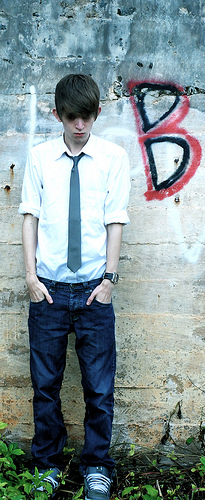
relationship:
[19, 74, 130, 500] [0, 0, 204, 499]
young man standing against wall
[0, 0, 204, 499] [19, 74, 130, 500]
wall behind young man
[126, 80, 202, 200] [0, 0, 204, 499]
graffiti painted on wall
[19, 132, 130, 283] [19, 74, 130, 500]
shirt worn on young man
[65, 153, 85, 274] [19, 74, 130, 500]
tie worn on young man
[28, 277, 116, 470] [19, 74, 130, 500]
jeans worn on young man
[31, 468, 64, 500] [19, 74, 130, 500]
skater shoe worn on young man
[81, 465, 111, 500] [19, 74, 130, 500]
skater shoe worn on young man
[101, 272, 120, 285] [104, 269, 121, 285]
watch worn on wrist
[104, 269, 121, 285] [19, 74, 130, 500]
wrist of young man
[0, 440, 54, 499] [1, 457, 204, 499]
plants growing on ground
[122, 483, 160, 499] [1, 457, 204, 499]
plants growing on ground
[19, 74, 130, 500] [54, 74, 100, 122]
young man with hair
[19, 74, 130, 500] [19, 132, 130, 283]
young man wearing shirt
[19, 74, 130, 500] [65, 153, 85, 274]
young man wearing tie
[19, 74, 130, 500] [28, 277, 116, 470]
young man wearing jeans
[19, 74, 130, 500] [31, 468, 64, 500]
young man wearing skater shoe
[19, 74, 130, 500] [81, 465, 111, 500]
young man wearing skater shoe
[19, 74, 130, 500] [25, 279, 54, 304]
young man with hand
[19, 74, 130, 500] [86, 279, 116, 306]
young man with hand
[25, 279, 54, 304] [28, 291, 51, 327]
hand stuck in pocket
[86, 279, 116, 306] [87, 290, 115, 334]
hand stuck in pocket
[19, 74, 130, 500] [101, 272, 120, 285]
young man wearing watch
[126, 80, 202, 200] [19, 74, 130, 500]
graffiti near young man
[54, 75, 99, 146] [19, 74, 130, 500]
head of young man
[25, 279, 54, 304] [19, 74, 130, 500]
hand of young man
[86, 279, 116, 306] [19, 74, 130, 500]
hand of young man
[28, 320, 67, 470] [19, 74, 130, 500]
leg of young man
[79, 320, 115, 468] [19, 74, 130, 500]
leg of young man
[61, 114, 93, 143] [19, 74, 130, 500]
face of young man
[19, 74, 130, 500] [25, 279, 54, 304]
young man standing with hand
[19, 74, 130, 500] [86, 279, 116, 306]
young man standing with hand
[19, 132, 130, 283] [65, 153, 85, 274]
shirt and tie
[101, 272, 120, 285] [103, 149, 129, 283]
watch on arm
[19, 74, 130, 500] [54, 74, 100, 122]
young man has hair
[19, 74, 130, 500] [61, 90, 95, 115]
young man has bangs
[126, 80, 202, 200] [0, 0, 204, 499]
graffiti written on wall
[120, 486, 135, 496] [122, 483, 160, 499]
leaf on plants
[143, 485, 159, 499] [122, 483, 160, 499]
leaf on plants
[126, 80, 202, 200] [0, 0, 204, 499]
graffiti spray painted on wall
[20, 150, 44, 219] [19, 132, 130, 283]
sleeve of shirt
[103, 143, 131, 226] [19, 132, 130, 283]
sleeve of shirt